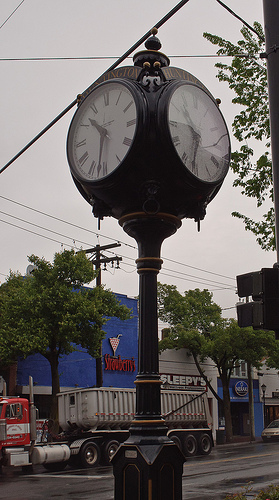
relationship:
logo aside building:
[96, 349, 145, 381] [66, 286, 225, 418]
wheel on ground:
[168, 435, 184, 456] [0, 439, 278, 499]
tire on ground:
[182, 431, 198, 460] [0, 439, 278, 499]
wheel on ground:
[197, 431, 210, 455] [0, 439, 278, 499]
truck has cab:
[0, 375, 214, 475] [0, 397, 29, 446]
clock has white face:
[66, 80, 139, 182] [97, 124, 215, 179]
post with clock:
[105, 214, 190, 497] [55, 14, 241, 243]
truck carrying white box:
[0, 369, 214, 471] [53, 379, 212, 431]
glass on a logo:
[108, 336, 120, 357] [105, 351, 138, 373]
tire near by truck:
[181, 431, 198, 457] [0, 375, 214, 475]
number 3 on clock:
[127, 118, 136, 127] [66, 80, 139, 182]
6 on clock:
[99, 157, 112, 178] [71, 79, 144, 185]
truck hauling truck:
[0, 369, 214, 471] [0, 369, 214, 471]